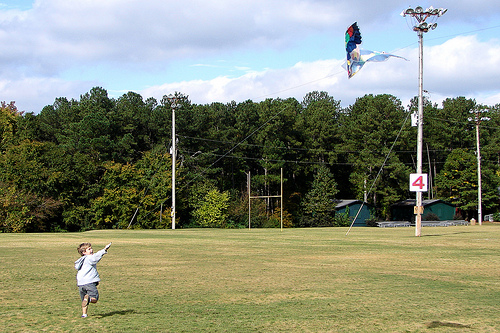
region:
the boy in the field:
[60, 221, 113, 327]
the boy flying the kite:
[45, 20, 392, 322]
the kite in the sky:
[325, 15, 415, 95]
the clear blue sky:
[225, 51, 331, 61]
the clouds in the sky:
[25, 16, 186, 56]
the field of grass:
[10, 235, 465, 317]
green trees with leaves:
[15, 95, 490, 215]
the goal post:
[236, 161, 287, 231]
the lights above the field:
[382, 5, 447, 235]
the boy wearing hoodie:
[71, 254, 110, 294]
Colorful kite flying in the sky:
[341, 18, 406, 78]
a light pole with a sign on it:
[407, 5, 447, 256]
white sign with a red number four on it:
[404, 164, 436, 206]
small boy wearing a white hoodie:
[57, 239, 112, 319]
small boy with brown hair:
[68, 239, 105, 319]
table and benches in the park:
[378, 216, 463, 228]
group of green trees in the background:
[1, 76, 137, 223]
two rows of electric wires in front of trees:
[179, 127, 384, 170]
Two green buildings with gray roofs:
[328, 192, 456, 227]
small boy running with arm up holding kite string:
[73, 229, 120, 321]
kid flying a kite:
[41, 235, 141, 315]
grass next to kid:
[156, 272, 230, 329]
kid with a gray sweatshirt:
[48, 223, 114, 308]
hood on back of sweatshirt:
[71, 254, 88, 269]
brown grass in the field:
[194, 258, 249, 299]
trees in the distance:
[22, 120, 127, 192]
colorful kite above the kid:
[314, 22, 389, 89]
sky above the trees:
[149, 9, 223, 52]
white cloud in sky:
[208, 13, 259, 38]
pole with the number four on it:
[383, 150, 444, 230]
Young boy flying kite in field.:
[65, 225, 120, 322]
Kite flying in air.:
[332, 21, 412, 86]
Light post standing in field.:
[397, 1, 452, 236]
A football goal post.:
[241, 164, 291, 235]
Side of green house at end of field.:
[332, 195, 374, 230]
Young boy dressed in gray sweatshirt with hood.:
[68, 245, 110, 286]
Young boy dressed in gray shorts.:
[76, 280, 102, 304]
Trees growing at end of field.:
[7, 82, 174, 229]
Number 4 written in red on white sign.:
[406, 168, 436, 193]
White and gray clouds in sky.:
[161, 8, 316, 88]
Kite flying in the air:
[341, 18, 366, 79]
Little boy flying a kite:
[72, 234, 119, 319]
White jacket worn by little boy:
[73, 250, 107, 285]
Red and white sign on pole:
[407, 170, 429, 192]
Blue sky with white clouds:
[3, 0, 498, 125]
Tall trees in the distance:
[0, 85, 498, 223]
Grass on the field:
[0, 227, 497, 330]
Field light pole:
[398, 0, 448, 236]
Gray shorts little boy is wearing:
[75, 280, 100, 300]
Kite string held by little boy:
[105, 59, 341, 248]